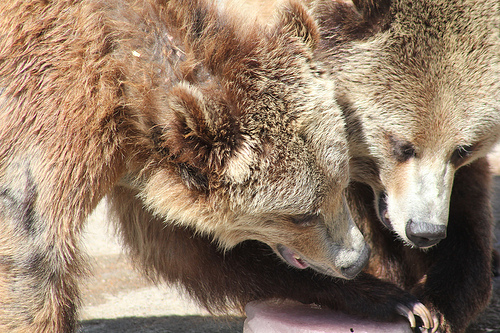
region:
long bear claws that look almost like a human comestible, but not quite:
[380, 292, 462, 332]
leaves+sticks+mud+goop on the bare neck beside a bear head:
[100, 14, 213, 84]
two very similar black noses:
[327, 217, 459, 287]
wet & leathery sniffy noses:
[334, 214, 457, 289]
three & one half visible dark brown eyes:
[275, 134, 480, 235]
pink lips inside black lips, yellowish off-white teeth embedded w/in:
[276, 185, 399, 275]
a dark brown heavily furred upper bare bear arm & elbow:
[0, 136, 67, 315]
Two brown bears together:
[161, 40, 490, 313]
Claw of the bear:
[387, 285, 451, 327]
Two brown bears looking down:
[91, 37, 488, 277]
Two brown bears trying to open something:
[77, 32, 490, 320]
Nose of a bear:
[411, 217, 446, 244]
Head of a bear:
[181, 30, 363, 287]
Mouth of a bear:
[374, 192, 391, 227]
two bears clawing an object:
[3, 8, 494, 324]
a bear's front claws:
[384, 285, 447, 325]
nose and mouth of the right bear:
[372, 156, 464, 257]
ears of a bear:
[152, 1, 330, 182]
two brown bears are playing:
[3, 3, 494, 328]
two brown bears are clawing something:
[16, 11, 493, 326]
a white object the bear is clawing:
[235, 280, 415, 332]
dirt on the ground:
[72, 201, 239, 330]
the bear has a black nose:
[406, 217, 450, 249]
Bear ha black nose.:
[410, 218, 459, 260]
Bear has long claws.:
[401, 300, 432, 330]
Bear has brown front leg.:
[461, 215, 489, 296]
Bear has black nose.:
[346, 250, 382, 299]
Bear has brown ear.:
[153, 97, 226, 156]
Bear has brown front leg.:
[19, 213, 64, 311]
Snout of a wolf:
[369, 167, 458, 257]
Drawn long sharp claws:
[390, 294, 449, 331]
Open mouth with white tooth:
[276, 237, 371, 283]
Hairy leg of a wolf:
[1, 106, 122, 331]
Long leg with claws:
[105, 244, 454, 331]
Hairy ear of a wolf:
[139, 70, 256, 190]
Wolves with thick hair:
[0, 1, 499, 331]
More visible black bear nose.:
[406, 219, 447, 249]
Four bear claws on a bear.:
[391, 296, 441, 331]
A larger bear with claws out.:
[1, 1, 437, 332]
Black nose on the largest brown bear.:
[337, 239, 372, 276]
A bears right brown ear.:
[166, 84, 218, 158]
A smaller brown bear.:
[287, 2, 497, 332]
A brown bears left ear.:
[284, 1, 321, 51]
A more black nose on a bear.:
[406, 220, 447, 248]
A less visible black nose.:
[341, 245, 373, 279]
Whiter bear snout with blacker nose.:
[393, 154, 455, 246]